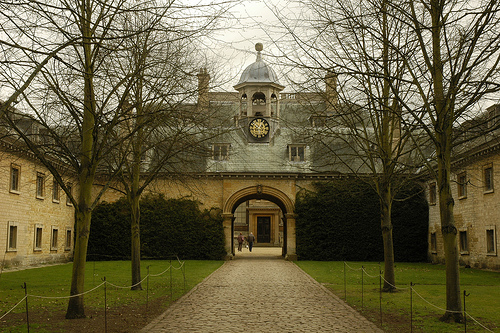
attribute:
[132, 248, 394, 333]
walkway — cobblestone, stone, narrow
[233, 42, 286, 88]
roof — blue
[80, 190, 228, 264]
ivy — green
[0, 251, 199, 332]
fence — rope, wire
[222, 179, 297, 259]
entryway — arched, stone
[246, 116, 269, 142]
clock — gold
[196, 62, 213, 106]
chimney — brick, stone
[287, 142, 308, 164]
window — dormer style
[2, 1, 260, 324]
tree — leafless, bare, without leaves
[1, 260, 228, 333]
grass — green, roped off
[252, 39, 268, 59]
cupola — circular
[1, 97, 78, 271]
building — brick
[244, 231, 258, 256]
person — walking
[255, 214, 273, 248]
door — wooden